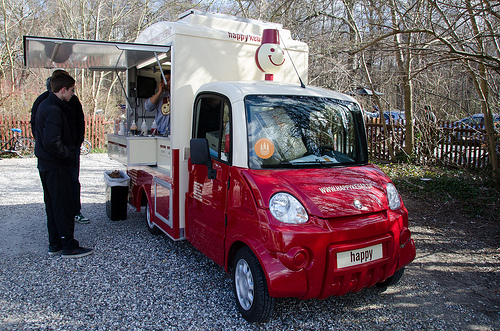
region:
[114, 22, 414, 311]
a small food truck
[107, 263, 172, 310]
pebbles on the ground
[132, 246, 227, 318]
pebbles on the ground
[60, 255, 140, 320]
pebbles on the ground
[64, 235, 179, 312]
pebbles on the ground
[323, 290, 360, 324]
pebbles on the ground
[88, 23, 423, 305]
truck is red and white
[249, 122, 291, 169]
orange decal on windshield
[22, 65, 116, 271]
people standing beside truck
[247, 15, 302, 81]
smiling face on truck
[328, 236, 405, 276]
white plate on front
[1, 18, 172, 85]
side door to truck open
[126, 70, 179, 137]
person inside the truck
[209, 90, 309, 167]
boxes inside the truck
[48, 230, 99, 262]
man's shoes are black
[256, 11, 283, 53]
character wearing red hat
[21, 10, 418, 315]
a food truck on a gravel road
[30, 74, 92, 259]
a man in all black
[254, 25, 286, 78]
a plastic clown atop a truck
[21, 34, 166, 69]
the window panel on a food truck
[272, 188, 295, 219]
the headlight on a truck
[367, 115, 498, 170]
a wooden fence near the road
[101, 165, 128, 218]
a garbage can sitting next to a truck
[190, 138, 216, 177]
a side window on the door of a truck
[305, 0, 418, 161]
a bare tree in the winter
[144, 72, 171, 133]
a man working in a food truck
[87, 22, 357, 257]
Small truck is white and red color.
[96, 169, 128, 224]
Trash is black and white color.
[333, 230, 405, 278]
Letters are red color.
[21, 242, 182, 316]
Road is grey color.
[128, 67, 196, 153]
One man is inside the truck to sell.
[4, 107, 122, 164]
Fence is brown color.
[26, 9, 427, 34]
Sky is blue color.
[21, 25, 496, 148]
Trees are behind the truck.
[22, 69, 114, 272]
Two people are standing in the road.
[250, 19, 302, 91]
Doll is in top of the truck.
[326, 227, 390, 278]
A license plate that says happy.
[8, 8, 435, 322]
A red food truck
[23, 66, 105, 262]
Two people in black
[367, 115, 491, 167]
A wooden picket fence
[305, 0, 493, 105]
Winter bare tres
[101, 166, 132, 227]
A trash can with liner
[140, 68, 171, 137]
Man working in the food truck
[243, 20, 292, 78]
A round head on top of the cab of the truck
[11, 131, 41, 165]
A spoked bicycle tire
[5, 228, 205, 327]
An area of gray gravel